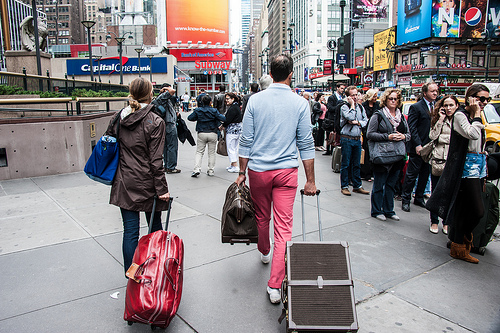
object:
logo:
[464, 7, 482, 26]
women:
[418, 95, 460, 235]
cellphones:
[466, 98, 483, 109]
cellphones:
[441, 109, 445, 114]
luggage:
[124, 196, 185, 330]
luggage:
[281, 189, 359, 332]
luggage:
[220, 182, 259, 246]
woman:
[218, 92, 242, 173]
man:
[235, 54, 317, 304]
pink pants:
[249, 168, 298, 289]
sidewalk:
[1, 95, 498, 330]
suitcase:
[281, 189, 360, 333]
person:
[366, 87, 412, 221]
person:
[340, 85, 370, 196]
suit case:
[124, 196, 185, 331]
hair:
[127, 77, 153, 113]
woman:
[424, 84, 488, 264]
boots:
[450, 242, 480, 264]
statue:
[19, 16, 49, 52]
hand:
[235, 174, 246, 187]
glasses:
[474, 96, 492, 102]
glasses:
[386, 97, 398, 101]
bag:
[84, 108, 125, 186]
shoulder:
[112, 107, 164, 120]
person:
[402, 82, 439, 212]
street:
[0, 112, 497, 332]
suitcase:
[221, 182, 259, 246]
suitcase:
[332, 146, 342, 173]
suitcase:
[446, 181, 498, 257]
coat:
[103, 103, 171, 212]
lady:
[104, 78, 172, 280]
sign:
[66, 56, 167, 75]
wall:
[51, 55, 173, 88]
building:
[334, 0, 500, 102]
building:
[267, 0, 353, 88]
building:
[0, 0, 242, 112]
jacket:
[104, 103, 170, 212]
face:
[476, 91, 489, 111]